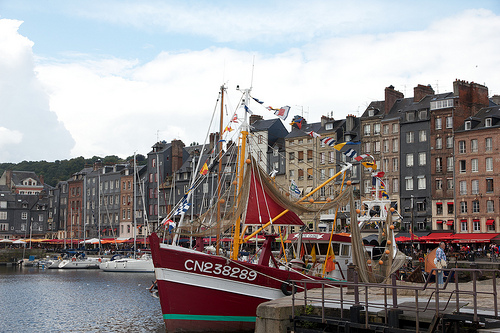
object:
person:
[432, 240, 449, 289]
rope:
[159, 150, 397, 292]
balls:
[386, 239, 393, 246]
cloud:
[0, 18, 60, 110]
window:
[417, 129, 428, 143]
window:
[404, 130, 416, 144]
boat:
[56, 172, 113, 270]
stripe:
[160, 312, 258, 324]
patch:
[44, 16, 88, 54]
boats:
[14, 210, 55, 266]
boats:
[46, 202, 94, 269]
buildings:
[282, 114, 323, 235]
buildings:
[356, 83, 407, 233]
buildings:
[400, 82, 454, 232]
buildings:
[428, 77, 489, 232]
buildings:
[452, 93, 500, 235]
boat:
[143, 80, 402, 333]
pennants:
[287, 113, 305, 130]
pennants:
[318, 135, 337, 148]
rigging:
[229, 129, 359, 280]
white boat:
[98, 148, 158, 273]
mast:
[230, 84, 253, 261]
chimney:
[387, 84, 396, 91]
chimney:
[248, 113, 264, 126]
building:
[243, 113, 290, 236]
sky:
[1, 1, 500, 166]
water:
[0, 263, 168, 333]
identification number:
[183, 258, 258, 281]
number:
[246, 270, 257, 282]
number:
[238, 269, 248, 280]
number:
[229, 267, 240, 279]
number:
[221, 265, 232, 276]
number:
[212, 263, 223, 275]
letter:
[193, 259, 204, 272]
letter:
[184, 259, 194, 271]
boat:
[56, 172, 120, 269]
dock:
[251, 275, 500, 333]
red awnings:
[435, 201, 443, 205]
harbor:
[0, 160, 500, 331]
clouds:
[359, 34, 440, 79]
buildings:
[146, 137, 189, 238]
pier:
[285, 266, 500, 333]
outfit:
[433, 246, 449, 285]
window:
[435, 219, 445, 231]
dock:
[0, 248, 154, 268]